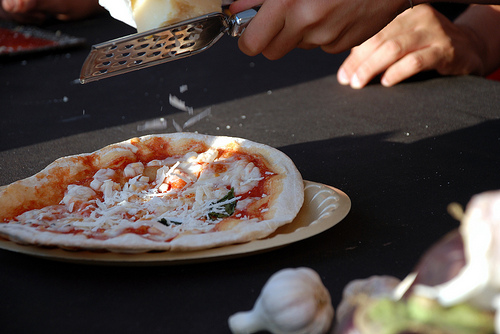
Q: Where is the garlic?
A: Near the plate.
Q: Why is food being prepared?
A: Because it's nearly dinner time.